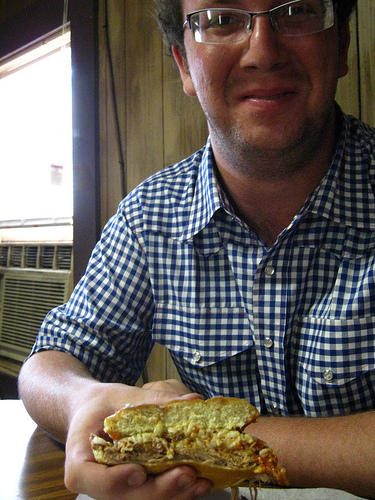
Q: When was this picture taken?
A: Day time.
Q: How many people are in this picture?
A: 1.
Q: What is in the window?
A: Air conditioner.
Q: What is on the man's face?
A: Glasses.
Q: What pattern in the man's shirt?
A: Gingham.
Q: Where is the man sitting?
A: At table.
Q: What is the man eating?
A: Sandwich.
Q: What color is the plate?
A: White.